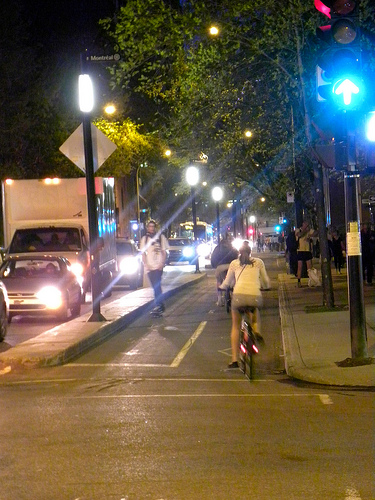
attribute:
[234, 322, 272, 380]
bike — black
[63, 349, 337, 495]
road — paved, black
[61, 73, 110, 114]
light — white, on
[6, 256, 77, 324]
car — white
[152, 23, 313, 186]
tree — green, heatlhy, full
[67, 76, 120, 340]
post — tall, black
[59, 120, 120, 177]
sign — metal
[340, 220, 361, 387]
sign — paper